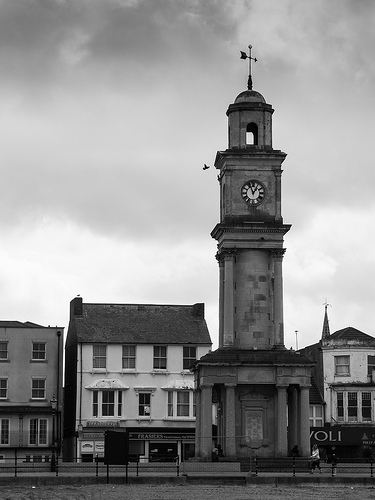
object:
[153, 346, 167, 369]
window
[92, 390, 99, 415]
window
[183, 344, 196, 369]
window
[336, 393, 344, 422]
window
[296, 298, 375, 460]
building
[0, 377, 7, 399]
window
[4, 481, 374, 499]
gray brick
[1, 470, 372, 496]
sidewalk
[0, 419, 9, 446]
window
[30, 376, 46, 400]
window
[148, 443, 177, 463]
black car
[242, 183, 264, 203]
clockface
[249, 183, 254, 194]
hands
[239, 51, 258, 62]
vane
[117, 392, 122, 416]
window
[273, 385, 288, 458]
pillar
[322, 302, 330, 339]
decoration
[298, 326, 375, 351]
roof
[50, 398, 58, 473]
lamp post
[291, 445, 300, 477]
post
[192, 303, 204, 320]
canopied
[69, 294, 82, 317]
canopied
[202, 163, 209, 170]
bird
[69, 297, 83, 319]
chimney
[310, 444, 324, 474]
children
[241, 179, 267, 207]
clock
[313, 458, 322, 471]
pants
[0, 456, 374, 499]
fence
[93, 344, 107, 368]
window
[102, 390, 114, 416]
window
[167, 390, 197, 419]
window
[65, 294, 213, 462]
building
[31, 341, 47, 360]
window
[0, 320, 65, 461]
building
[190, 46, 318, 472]
clock tower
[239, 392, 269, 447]
door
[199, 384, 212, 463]
pillars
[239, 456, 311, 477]
bench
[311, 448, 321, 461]
shirt